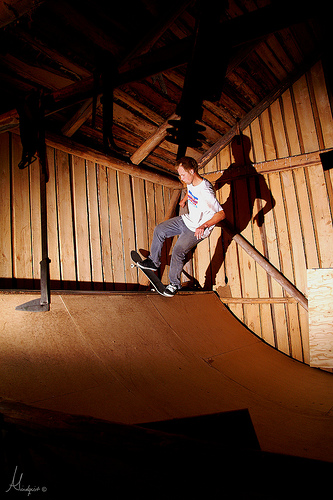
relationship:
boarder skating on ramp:
[137, 155, 226, 297] [0, 287, 333, 465]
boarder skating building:
[137, 155, 226, 297] [1, 27, 332, 449]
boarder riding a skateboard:
[137, 155, 226, 297] [123, 241, 175, 307]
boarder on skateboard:
[137, 155, 226, 297] [139, 261, 165, 294]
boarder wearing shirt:
[137, 155, 226, 297] [184, 187, 217, 226]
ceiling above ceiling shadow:
[2, 0, 325, 174] [138, 133, 276, 291]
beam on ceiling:
[9, 13, 165, 129] [2, 0, 325, 174]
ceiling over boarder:
[2, 0, 325, 174] [137, 155, 226, 297]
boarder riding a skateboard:
[137, 155, 226, 297] [126, 245, 169, 298]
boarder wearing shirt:
[137, 155, 226, 297] [178, 179, 224, 241]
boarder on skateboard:
[137, 155, 226, 297] [126, 245, 169, 298]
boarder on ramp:
[137, 155, 226, 297] [0, 287, 332, 499]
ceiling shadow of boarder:
[138, 133, 276, 291] [137, 155, 226, 297]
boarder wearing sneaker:
[137, 155, 226, 297] [136, 257, 155, 266]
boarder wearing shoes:
[137, 155, 226, 297] [134, 255, 158, 272]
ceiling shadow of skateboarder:
[138, 133, 276, 291] [130, 152, 233, 306]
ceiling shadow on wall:
[138, 133, 276, 291] [197, 49, 325, 374]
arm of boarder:
[214, 200, 236, 234] [138, 153, 210, 266]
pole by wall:
[25, 151, 74, 310] [50, 140, 197, 282]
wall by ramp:
[0, 128, 184, 290] [2, 292, 271, 409]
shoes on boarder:
[128, 255, 170, 300] [137, 155, 226, 297]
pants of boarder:
[151, 214, 195, 286] [137, 155, 226, 297]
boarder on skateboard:
[137, 155, 226, 297] [126, 244, 184, 302]